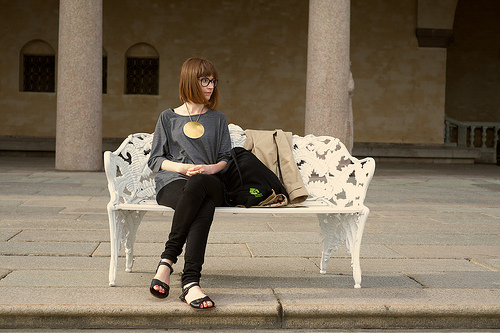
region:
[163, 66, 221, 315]
this is a lady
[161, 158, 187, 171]
thew lady is light skinned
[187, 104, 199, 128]
this is a necklace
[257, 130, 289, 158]
this is a jacket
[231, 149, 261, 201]
this is a bag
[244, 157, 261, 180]
the bag is black in color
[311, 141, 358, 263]
this is a bench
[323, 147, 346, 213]
the bench is white in color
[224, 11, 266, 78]
this is a wall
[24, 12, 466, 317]
Woman sitting on a white bench.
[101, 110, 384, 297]
A white decorative bench.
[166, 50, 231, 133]
Woman with brown hair.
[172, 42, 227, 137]
Woman wearing black glasses.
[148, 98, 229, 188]
A dark grey top.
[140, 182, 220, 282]
A pair of black pants.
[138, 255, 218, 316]
A pair of black shoes.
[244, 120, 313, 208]
A tan coat draped over bench.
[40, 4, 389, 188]
Two support columns in the background.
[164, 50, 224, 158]
A round gold necklace.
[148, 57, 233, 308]
woman ina grey long sleeve t-shirt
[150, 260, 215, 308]
black sandals on woman's feet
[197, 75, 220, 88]
eye-wear on the woman's eyes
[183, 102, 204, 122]
necklace on the woman's neck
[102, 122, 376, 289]
white metal bench in a rest area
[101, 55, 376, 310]
red hair woman sitting on white bench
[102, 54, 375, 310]
young in blank pants sitting on a white bench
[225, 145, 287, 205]
black bag beside the woman on the bench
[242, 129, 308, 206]
tan jacket on the bench under the the bag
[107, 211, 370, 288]
four legs on a white table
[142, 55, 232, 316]
woman on metal bench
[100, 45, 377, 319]
woman on white bench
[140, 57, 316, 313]
woman with tan coat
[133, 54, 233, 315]
woman with sandals on feet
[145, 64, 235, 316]
woman with yellow circle on her chest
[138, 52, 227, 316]
woman wearing glasses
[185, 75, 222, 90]
glasses with dark rims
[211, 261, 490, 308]
shadow of woman and bench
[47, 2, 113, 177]
massive column behind woman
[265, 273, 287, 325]
crack in joint between slabs of stone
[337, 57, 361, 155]
a person behind a column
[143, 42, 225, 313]
a girl sitting on a bench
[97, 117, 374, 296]
a white bench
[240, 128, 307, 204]
a tan jacket on the bench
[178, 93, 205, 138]
a big necklace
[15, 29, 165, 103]
three windows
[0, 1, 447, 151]
an orange wall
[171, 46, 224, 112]
the head of a girl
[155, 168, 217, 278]
black pants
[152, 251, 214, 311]
the sandals that a girl is wearing